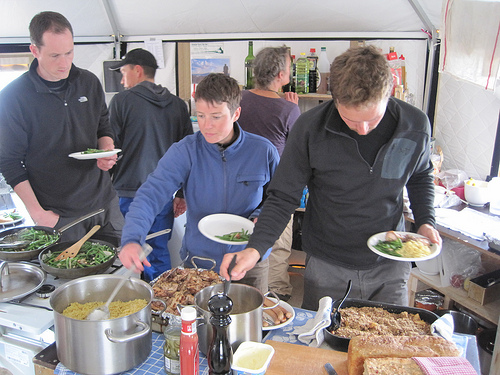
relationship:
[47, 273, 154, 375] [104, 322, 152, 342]
pot has a handle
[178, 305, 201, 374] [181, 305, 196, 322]
bottle has lid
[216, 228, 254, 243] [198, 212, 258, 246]
food on plate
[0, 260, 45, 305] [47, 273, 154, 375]
lid for pot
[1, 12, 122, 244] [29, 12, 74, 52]
guy has short hair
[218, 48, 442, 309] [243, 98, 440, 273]
guy wearing shirt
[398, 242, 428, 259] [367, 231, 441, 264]
food on a plate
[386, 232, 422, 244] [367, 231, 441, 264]
food on a plate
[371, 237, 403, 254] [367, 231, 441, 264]
food on a plate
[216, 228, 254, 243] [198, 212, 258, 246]
food on a plate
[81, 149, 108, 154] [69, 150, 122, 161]
food on a plate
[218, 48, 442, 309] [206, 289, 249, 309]
guy getting food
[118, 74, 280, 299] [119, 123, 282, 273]
lady wearing sweater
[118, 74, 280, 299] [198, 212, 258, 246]
lady holding plate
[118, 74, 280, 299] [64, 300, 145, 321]
lady getting food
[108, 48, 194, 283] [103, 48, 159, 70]
guy wearing cap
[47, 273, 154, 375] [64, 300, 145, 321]
pot of food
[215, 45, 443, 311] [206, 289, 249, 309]
man getting food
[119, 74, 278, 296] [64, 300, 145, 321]
person getting food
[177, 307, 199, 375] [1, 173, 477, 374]
ketchup on top of table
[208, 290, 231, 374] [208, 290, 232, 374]
grinder for pepper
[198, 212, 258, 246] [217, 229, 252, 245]
plate of beans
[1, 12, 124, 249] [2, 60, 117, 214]
person wearing grey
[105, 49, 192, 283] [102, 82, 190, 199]
person wearing grey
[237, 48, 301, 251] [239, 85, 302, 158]
person wearing grey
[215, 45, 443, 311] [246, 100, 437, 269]
man wearing grey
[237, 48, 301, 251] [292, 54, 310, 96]
person looking at food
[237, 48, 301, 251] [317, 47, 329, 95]
person looking at food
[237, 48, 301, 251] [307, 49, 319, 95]
person looking at food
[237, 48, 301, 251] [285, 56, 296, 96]
person looking at food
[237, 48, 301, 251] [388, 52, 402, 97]
person looking at food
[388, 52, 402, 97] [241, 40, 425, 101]
food on shelf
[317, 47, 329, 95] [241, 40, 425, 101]
food on shelf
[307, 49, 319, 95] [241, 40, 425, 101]
food on shelf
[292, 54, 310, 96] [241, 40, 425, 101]
food on shelf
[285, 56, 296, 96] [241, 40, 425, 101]
food on shelf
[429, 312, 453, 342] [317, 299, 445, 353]
towel on a pan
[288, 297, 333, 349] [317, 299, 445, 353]
towel on a pan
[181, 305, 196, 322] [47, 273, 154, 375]
lid to a pot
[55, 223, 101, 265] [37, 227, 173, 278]
spoon in a pan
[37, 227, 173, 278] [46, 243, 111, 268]
pan of salad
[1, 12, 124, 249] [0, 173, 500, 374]
person at a buffet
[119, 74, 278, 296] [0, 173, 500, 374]
person at a buffet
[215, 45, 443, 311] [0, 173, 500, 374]
man at a buffet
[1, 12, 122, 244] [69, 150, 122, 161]
guy holding plate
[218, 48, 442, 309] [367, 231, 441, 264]
guy holding plate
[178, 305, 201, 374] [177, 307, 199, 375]
bottle of ketchup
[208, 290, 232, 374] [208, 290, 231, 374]
pepper in grinder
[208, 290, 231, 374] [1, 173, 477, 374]
grinder on top of table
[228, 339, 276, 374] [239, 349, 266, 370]
container of margerine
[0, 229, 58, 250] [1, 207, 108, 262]
beans in a pan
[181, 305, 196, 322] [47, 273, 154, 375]
lid of a pot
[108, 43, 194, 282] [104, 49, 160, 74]
guy wearing a hat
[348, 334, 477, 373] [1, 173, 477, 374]
bread on top of table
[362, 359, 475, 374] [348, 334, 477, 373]
loaf of bread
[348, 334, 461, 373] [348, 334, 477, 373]
loaf of bread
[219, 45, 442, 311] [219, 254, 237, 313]
man holding ladle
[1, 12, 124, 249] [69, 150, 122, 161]
person holding plate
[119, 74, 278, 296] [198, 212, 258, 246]
person holding plate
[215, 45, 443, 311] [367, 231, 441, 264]
man holding plate